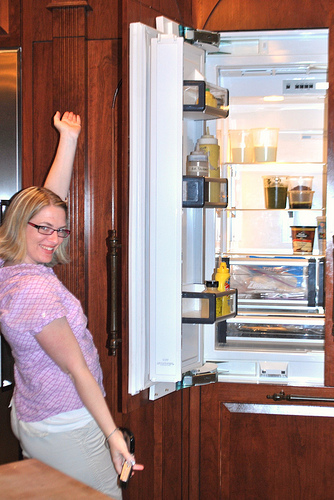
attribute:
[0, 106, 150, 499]
woman — posing, young, smiling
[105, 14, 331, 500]
refrigerator — open, built in, holding left overs, filled with food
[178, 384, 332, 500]
door — closed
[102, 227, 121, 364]
handle — large, wooden, metal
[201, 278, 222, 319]
bottle — mustard, sauce, squeeze type, plastic, home made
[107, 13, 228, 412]
door — white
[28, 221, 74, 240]
glasses — plastic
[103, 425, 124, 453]
bracelet — thin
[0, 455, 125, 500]
counter — wooden, brown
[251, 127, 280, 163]
container — plastic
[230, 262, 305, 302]
lunch meat — in drawer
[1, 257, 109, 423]
blouse — purple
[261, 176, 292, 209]
cup — plastic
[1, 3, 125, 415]
paneling — wood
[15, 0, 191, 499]
cabinet — brown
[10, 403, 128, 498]
shorts — beige